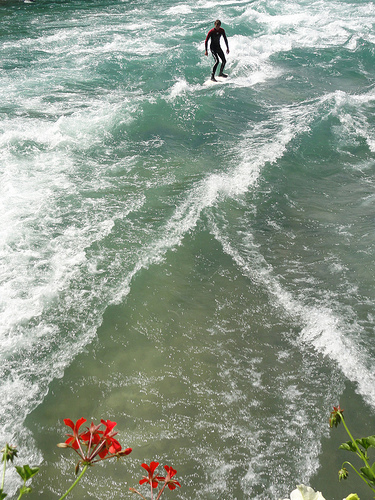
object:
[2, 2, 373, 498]
water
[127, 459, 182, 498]
flowers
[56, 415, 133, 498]
flowers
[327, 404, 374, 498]
flowers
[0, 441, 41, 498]
flowers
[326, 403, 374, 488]
stem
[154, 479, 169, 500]
stem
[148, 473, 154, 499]
stem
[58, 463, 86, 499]
stem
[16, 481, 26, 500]
stem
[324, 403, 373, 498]
plant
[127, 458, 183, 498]
plant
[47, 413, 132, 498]
plant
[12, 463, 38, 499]
plant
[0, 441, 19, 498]
plant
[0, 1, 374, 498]
waves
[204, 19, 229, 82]
man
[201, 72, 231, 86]
surfboard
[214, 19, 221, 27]
hair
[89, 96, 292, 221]
riddles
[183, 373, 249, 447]
ripples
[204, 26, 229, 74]
wet suit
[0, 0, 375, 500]
stream